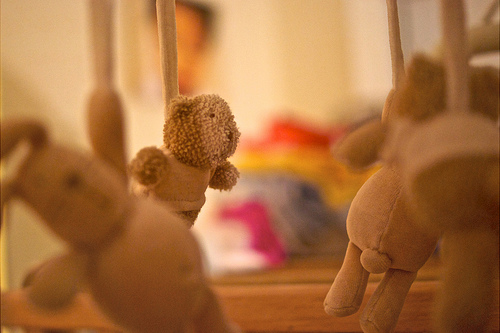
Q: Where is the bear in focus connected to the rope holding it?
A: Its stomach.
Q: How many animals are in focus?
A: One.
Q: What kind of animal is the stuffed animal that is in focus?
A: Bear.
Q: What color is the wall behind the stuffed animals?
A: White.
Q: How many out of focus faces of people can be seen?
A: One.